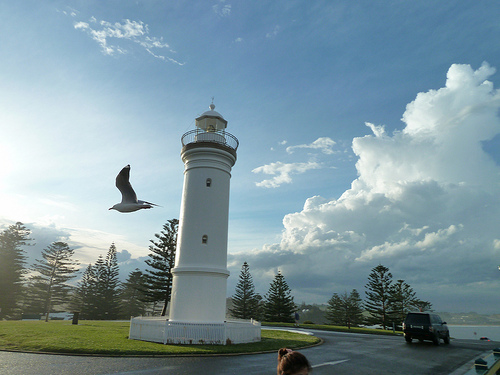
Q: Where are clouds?
A: In the sky.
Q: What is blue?
A: The sky.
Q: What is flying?
A: A bird.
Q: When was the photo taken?
A: Daytime.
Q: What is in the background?
A: Trees.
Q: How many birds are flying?
A: One.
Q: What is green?
A: The grass.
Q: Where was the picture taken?
A: At a lighthouse.